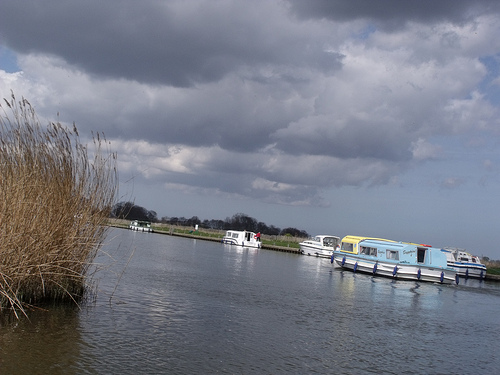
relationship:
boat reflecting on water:
[332, 235, 458, 284] [1, 223, 499, 374]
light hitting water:
[147, 287, 167, 329] [169, 252, 352, 373]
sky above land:
[21, 18, 486, 243] [139, 178, 269, 245]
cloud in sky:
[2, 1, 366, 90] [2, 2, 497, 286]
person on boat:
[253, 227, 269, 243] [338, 230, 463, 299]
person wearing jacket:
[253, 227, 269, 243] [253, 230, 263, 240]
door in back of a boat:
[418, 248, 426, 263] [332, 235, 458, 284]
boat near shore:
[297, 234, 339, 257] [97, 216, 300, 249]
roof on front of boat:
[335, 234, 423, 254] [302, 231, 453, 281]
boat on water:
[332, 235, 458, 284] [102, 285, 497, 373]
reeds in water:
[1, 92, 121, 321] [124, 227, 359, 357]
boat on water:
[223, 230, 262, 249] [192, 261, 320, 353]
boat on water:
[454, 247, 488, 284] [200, 270, 386, 337]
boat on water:
[337, 230, 458, 291] [200, 270, 386, 337]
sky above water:
[21, 18, 486, 243] [11, 211, 498, 366]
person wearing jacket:
[256, 232, 261, 242] [256, 233, 261, 238]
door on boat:
[410, 240, 431, 265] [332, 235, 458, 284]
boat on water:
[223, 230, 262, 249] [1, 223, 499, 374]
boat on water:
[332, 235, 458, 284] [1, 223, 499, 374]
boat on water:
[436, 247, 487, 278] [1, 223, 499, 374]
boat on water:
[299, 235, 341, 258] [1, 223, 499, 374]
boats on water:
[128, 220, 150, 231] [1, 223, 499, 374]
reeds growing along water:
[1, 88, 122, 324] [1, 223, 499, 374]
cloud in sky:
[2, 1, 500, 208] [2, 2, 497, 286]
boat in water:
[223, 230, 262, 249] [228, 250, 285, 277]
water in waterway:
[1, 223, 499, 374] [0, 220, 499, 374]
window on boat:
[387, 250, 400, 262] [336, 234, 454, 279]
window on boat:
[359, 247, 379, 256] [336, 234, 454, 279]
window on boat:
[339, 241, 352, 249] [336, 234, 454, 279]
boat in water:
[221, 229, 262, 248] [1, 223, 499, 374]